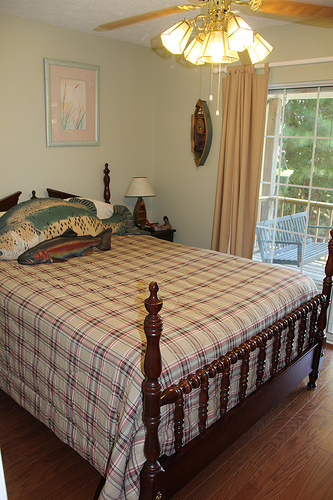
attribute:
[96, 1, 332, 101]
celing fan — light, beige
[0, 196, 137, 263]
pillows — fish, colorful, stuffed, plush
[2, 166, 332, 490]
bed — wooden, dark, king sized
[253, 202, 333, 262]
bench — hanging, blue, green, swing, wooden, slatted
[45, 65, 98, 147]
picture — hanging, framed, decorative, pink, small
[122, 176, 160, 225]
lamp — boat shaped, small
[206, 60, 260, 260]
curtains — opened, tan, beige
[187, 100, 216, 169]
boat decor — small, wooden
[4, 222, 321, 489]
bed spread — plaid, checked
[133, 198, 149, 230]
canoe — lamp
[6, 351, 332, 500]
floor — hardwood, wooden, dark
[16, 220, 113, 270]
fish — fake, pillow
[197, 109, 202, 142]
fish — fake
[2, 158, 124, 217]
head board — wooden